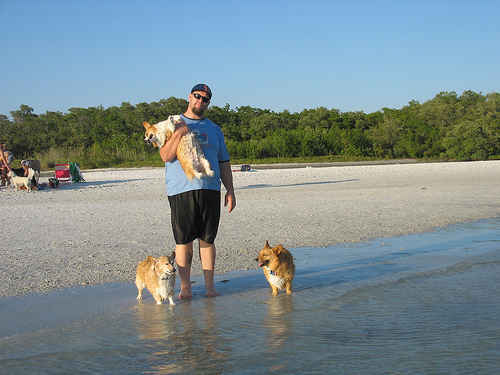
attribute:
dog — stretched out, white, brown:
[141, 113, 216, 181]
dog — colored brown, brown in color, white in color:
[255, 241, 299, 301]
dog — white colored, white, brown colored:
[128, 239, 179, 313]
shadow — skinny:
[197, 236, 488, 290]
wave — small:
[334, 253, 499, 326]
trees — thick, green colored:
[1, 89, 496, 165]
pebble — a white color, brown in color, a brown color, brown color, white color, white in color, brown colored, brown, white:
[75, 275, 90, 286]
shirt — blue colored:
[163, 112, 231, 193]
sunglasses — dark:
[189, 90, 215, 105]